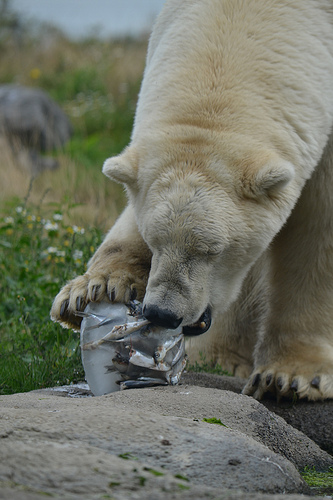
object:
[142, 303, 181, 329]
nose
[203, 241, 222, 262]
eyes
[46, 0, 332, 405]
bear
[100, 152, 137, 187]
ear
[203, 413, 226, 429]
moss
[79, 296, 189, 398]
block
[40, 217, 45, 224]
white flower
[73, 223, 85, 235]
white flower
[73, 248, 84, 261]
white flower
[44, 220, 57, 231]
white flower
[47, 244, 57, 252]
white flower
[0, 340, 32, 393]
grass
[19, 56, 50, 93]
flower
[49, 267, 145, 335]
claw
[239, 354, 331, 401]
claw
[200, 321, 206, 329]
tooth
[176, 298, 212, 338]
mouth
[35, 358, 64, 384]
grass`s part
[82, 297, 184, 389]
fish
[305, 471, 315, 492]
plant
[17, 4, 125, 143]
background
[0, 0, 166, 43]
sky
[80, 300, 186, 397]
base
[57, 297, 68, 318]
nail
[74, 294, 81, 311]
nail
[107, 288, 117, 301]
nail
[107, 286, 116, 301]
nail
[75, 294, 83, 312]
nail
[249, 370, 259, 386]
nail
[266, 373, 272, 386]
nail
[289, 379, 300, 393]
nail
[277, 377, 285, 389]
nail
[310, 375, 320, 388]
nail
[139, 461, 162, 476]
moss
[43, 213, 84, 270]
flowers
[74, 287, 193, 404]
ice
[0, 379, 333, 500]
rock